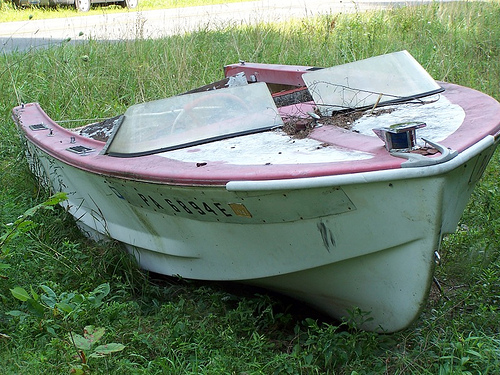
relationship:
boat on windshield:
[13, 50, 498, 331] [100, 51, 437, 155]